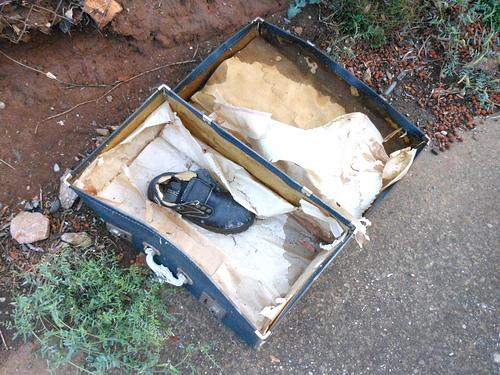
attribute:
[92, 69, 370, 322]
box — old, abandoned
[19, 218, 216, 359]
vegetation — green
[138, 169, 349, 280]
paper — torn, old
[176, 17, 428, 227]
paper — white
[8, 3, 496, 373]
ground — brown, sand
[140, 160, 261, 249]
shoe — old, black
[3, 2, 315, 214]
sand — brown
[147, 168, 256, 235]
shoe — old, worn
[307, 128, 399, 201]
paper — white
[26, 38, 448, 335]
ground — brown, sand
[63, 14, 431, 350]
box — blue, cardboard, old, torn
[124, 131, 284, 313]
shoe — black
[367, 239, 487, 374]
ground — grey, tarmac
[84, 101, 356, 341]
paper — dirty, stained